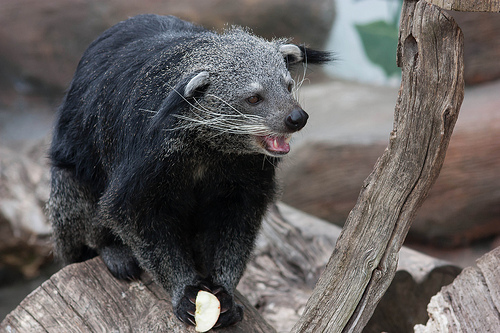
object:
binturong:
[47, 12, 335, 329]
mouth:
[254, 131, 294, 156]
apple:
[192, 289, 222, 332]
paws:
[171, 283, 209, 328]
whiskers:
[206, 92, 262, 125]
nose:
[285, 109, 311, 129]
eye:
[243, 95, 265, 105]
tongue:
[265, 135, 289, 152]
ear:
[183, 70, 209, 97]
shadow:
[362, 264, 462, 332]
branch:
[291, 0, 464, 332]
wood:
[4, 243, 279, 332]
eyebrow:
[240, 82, 264, 96]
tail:
[45, 165, 95, 267]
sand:
[205, 63, 207, 65]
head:
[174, 31, 307, 158]